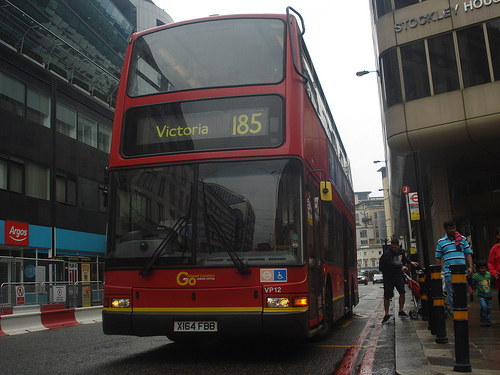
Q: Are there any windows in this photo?
A: Yes, there is a window.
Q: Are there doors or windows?
A: Yes, there is a window.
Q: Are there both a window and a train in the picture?
A: No, there is a window but no trains.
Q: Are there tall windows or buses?
A: Yes, there is a tall window.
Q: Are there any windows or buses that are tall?
A: Yes, the window is tall.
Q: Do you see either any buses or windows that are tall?
A: Yes, the window is tall.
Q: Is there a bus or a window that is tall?
A: Yes, the window is tall.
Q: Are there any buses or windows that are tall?
A: Yes, the window is tall.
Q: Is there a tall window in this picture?
A: Yes, there is a tall window.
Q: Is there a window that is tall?
A: Yes, there is a window that is tall.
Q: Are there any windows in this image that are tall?
A: Yes, there is a window that is tall.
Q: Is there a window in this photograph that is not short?
A: Yes, there is a tall window.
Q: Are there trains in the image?
A: No, there are no trains.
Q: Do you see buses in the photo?
A: Yes, there is a bus.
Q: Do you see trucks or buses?
A: Yes, there is a bus.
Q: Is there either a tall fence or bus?
A: Yes, there is a tall bus.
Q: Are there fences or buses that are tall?
A: Yes, the bus is tall.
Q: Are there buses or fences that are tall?
A: Yes, the bus is tall.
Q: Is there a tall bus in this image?
A: Yes, there is a tall bus.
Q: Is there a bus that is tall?
A: Yes, there is a bus that is tall.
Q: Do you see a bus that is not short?
A: Yes, there is a tall bus.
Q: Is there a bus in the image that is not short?
A: Yes, there is a tall bus.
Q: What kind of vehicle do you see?
A: The vehicle is a bus.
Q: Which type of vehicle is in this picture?
A: The vehicle is a bus.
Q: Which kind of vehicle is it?
A: The vehicle is a bus.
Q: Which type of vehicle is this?
A: This is a bus.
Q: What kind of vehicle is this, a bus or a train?
A: This is a bus.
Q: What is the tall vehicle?
A: The vehicle is a bus.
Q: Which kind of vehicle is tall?
A: The vehicle is a bus.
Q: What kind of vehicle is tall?
A: The vehicle is a bus.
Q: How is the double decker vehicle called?
A: The vehicle is a bus.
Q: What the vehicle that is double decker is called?
A: The vehicle is a bus.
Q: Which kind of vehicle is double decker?
A: The vehicle is a bus.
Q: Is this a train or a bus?
A: This is a bus.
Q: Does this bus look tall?
A: Yes, the bus is tall.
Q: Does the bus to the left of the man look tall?
A: Yes, the bus is tall.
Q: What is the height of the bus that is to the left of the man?
A: The bus is tall.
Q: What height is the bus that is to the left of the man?
A: The bus is tall.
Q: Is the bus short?
A: No, the bus is tall.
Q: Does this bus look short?
A: No, the bus is tall.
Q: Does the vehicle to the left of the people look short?
A: No, the bus is tall.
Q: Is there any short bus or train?
A: No, there is a bus but it is tall.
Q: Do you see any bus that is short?
A: No, there is a bus but it is tall.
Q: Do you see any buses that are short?
A: No, there is a bus but it is tall.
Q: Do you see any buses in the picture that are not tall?
A: No, there is a bus but it is tall.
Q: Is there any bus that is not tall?
A: No, there is a bus but it is tall.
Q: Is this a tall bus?
A: Yes, this is a tall bus.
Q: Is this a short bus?
A: No, this is a tall bus.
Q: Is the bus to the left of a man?
A: Yes, the bus is to the left of a man.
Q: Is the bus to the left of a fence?
A: No, the bus is to the left of a man.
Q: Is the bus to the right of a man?
A: No, the bus is to the left of a man.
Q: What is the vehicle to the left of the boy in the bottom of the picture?
A: The vehicle is a bus.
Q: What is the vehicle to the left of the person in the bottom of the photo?
A: The vehicle is a bus.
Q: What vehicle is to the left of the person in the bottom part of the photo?
A: The vehicle is a bus.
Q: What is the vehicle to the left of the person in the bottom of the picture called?
A: The vehicle is a bus.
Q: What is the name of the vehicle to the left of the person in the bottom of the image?
A: The vehicle is a bus.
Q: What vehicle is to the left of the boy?
A: The vehicle is a bus.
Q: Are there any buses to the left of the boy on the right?
A: Yes, there is a bus to the left of the boy.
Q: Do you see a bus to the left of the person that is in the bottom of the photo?
A: Yes, there is a bus to the left of the boy.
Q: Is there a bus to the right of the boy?
A: No, the bus is to the left of the boy.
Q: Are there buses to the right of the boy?
A: No, the bus is to the left of the boy.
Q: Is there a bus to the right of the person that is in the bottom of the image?
A: No, the bus is to the left of the boy.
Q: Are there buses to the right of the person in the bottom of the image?
A: No, the bus is to the left of the boy.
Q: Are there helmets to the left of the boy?
A: No, there is a bus to the left of the boy.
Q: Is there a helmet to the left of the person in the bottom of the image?
A: No, there is a bus to the left of the boy.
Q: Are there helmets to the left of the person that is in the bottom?
A: No, there is a bus to the left of the boy.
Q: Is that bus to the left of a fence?
A: No, the bus is to the left of a boy.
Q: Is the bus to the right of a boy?
A: No, the bus is to the left of a boy.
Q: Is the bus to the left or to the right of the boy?
A: The bus is to the left of the boy.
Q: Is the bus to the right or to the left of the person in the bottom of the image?
A: The bus is to the left of the boy.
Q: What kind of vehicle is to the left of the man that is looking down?
A: The vehicle is a bus.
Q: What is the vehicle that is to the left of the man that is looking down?
A: The vehicle is a bus.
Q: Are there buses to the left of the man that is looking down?
A: Yes, there is a bus to the left of the man.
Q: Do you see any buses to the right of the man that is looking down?
A: No, the bus is to the left of the man.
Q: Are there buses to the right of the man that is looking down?
A: No, the bus is to the left of the man.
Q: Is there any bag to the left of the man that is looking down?
A: No, there is a bus to the left of the man.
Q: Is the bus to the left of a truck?
A: No, the bus is to the left of a man.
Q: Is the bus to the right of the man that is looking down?
A: No, the bus is to the left of the man.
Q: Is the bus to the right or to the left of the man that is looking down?
A: The bus is to the left of the man.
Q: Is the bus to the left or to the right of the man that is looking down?
A: The bus is to the left of the man.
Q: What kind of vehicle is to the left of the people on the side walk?
A: The vehicle is a bus.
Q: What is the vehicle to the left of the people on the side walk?
A: The vehicle is a bus.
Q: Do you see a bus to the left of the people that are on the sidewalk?
A: Yes, there is a bus to the left of the people.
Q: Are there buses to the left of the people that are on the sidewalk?
A: Yes, there is a bus to the left of the people.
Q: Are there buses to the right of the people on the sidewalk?
A: No, the bus is to the left of the people.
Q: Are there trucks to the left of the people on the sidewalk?
A: No, there is a bus to the left of the people.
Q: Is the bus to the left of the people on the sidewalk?
A: Yes, the bus is to the left of the people.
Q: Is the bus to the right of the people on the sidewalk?
A: No, the bus is to the left of the people.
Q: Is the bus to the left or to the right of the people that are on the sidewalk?
A: The bus is to the left of the people.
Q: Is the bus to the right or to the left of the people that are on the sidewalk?
A: The bus is to the left of the people.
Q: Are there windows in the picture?
A: Yes, there is a window.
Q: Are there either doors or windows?
A: Yes, there is a window.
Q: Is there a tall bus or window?
A: Yes, there is a tall window.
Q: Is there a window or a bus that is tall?
A: Yes, the window is tall.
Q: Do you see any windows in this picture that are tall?
A: Yes, there is a tall window.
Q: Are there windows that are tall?
A: Yes, there is a window that is tall.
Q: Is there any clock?
A: No, there are no clocks.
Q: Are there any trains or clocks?
A: No, there are no clocks or trains.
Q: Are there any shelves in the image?
A: No, there are no shelves.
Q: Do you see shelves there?
A: No, there are no shelves.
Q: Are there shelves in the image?
A: No, there are no shelves.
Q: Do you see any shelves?
A: No, there are no shelves.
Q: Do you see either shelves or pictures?
A: No, there are no shelves or pictures.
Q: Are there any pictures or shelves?
A: No, there are no shelves or pictures.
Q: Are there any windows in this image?
A: Yes, there is a window.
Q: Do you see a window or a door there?
A: Yes, there is a window.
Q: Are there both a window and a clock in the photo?
A: No, there is a window but no clocks.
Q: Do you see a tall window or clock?
A: Yes, there is a tall window.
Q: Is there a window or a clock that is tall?
A: Yes, the window is tall.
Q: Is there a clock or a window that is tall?
A: Yes, the window is tall.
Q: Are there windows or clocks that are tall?
A: Yes, the window is tall.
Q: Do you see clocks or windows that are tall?
A: Yes, the window is tall.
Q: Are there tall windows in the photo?
A: Yes, there is a tall window.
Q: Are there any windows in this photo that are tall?
A: Yes, there is a window that is tall.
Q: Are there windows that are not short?
A: Yes, there is a tall window.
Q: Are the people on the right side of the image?
A: Yes, the people are on the right of the image.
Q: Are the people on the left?
A: No, the people are on the right of the image.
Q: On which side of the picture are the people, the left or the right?
A: The people are on the right of the image.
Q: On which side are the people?
A: The people are on the right of the image.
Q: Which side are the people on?
A: The people are on the right of the image.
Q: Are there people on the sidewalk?
A: Yes, there are people on the sidewalk.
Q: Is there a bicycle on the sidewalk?
A: No, there are people on the sidewalk.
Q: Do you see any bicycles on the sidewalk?
A: No, there are people on the sidewalk.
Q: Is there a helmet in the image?
A: No, there are no helmets.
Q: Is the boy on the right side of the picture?
A: Yes, the boy is on the right of the image.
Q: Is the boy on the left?
A: No, the boy is on the right of the image.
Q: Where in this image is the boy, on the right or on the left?
A: The boy is on the right of the image.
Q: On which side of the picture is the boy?
A: The boy is on the right of the image.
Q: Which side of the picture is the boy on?
A: The boy is on the right of the image.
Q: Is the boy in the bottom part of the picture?
A: Yes, the boy is in the bottom of the image.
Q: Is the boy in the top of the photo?
A: No, the boy is in the bottom of the image.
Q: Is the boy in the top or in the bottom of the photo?
A: The boy is in the bottom of the image.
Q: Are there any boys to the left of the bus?
A: No, the boy is to the right of the bus.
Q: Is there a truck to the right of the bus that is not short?
A: No, there is a boy to the right of the bus.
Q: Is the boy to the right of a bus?
A: Yes, the boy is to the right of a bus.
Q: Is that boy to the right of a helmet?
A: No, the boy is to the right of a bus.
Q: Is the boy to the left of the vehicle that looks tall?
A: No, the boy is to the right of the bus.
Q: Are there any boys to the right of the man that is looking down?
A: Yes, there is a boy to the right of the man.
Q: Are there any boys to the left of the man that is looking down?
A: No, the boy is to the right of the man.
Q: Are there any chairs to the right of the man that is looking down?
A: No, there is a boy to the right of the man.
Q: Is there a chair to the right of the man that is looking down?
A: No, there is a boy to the right of the man.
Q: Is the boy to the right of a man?
A: Yes, the boy is to the right of a man.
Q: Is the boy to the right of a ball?
A: No, the boy is to the right of a man.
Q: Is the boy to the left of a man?
A: No, the boy is to the right of a man.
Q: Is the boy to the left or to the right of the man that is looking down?
A: The boy is to the right of the man.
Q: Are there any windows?
A: Yes, there is a window.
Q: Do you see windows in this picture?
A: Yes, there is a window.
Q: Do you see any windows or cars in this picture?
A: Yes, there is a window.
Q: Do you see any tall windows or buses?
A: Yes, there is a tall window.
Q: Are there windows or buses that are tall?
A: Yes, the window is tall.